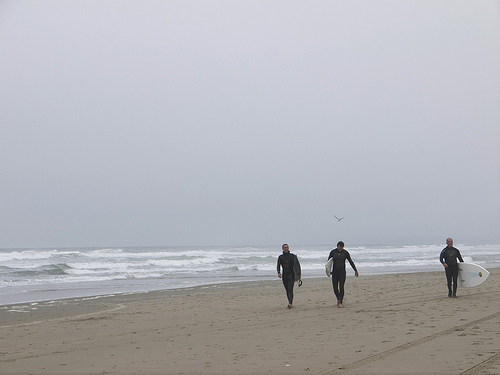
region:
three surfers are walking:
[276, 237, 490, 309]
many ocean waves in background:
[1, 243, 498, 288]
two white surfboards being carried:
[323, 255, 490, 288]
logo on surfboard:
[478, 270, 483, 277]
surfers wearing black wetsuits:
[276, 246, 463, 306]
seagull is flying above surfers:
[333, 213, 345, 223]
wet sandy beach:
[0, 266, 498, 373]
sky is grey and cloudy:
[0, 0, 499, 248]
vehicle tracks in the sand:
[319, 310, 499, 374]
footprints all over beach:
[0, 267, 499, 374]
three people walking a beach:
[271, 233, 461, 314]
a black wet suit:
[320, 242, 355, 307]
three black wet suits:
[260, 232, 466, 312]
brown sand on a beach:
[80, 292, 492, 372]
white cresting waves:
[0, 241, 270, 276]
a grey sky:
[0, 5, 490, 205]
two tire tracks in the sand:
[341, 304, 496, 372]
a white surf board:
[447, 253, 492, 294]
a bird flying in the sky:
[324, 207, 352, 228]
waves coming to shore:
[0, 280, 207, 331]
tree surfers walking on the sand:
[256, 228, 493, 312]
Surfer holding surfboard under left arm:
[429, 233, 496, 301]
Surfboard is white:
[435, 261, 495, 292]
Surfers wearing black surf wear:
[264, 228, 470, 310]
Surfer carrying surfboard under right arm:
[322, 234, 363, 314]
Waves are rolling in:
[0, 239, 498, 305]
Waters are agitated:
[6, 241, 498, 293]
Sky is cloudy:
[8, 96, 489, 243]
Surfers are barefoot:
[264, 228, 367, 318]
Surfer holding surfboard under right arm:
[265, 239, 310, 314]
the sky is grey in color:
[2, 0, 495, 244]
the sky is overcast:
[3, 6, 485, 249]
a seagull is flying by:
[334, 213, 346, 223]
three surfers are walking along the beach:
[266, 238, 493, 311]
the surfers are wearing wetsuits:
[273, 230, 488, 308]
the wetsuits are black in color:
[272, 229, 467, 313]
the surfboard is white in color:
[438, 260, 489, 290]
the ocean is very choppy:
[1, 243, 486, 290]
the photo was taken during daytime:
[2, 2, 484, 367]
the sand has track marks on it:
[0, 271, 498, 369]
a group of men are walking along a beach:
[238, 235, 493, 332]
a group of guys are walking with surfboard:
[203, 217, 498, 317]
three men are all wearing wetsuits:
[236, 211, 496, 322]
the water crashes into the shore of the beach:
[9, 244, 256, 299]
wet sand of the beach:
[80, 301, 432, 370]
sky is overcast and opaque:
[35, 14, 483, 234]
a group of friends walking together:
[253, 228, 496, 333]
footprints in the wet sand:
[399, 318, 421, 335]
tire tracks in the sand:
[341, 327, 456, 370]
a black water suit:
[430, 247, 463, 299]